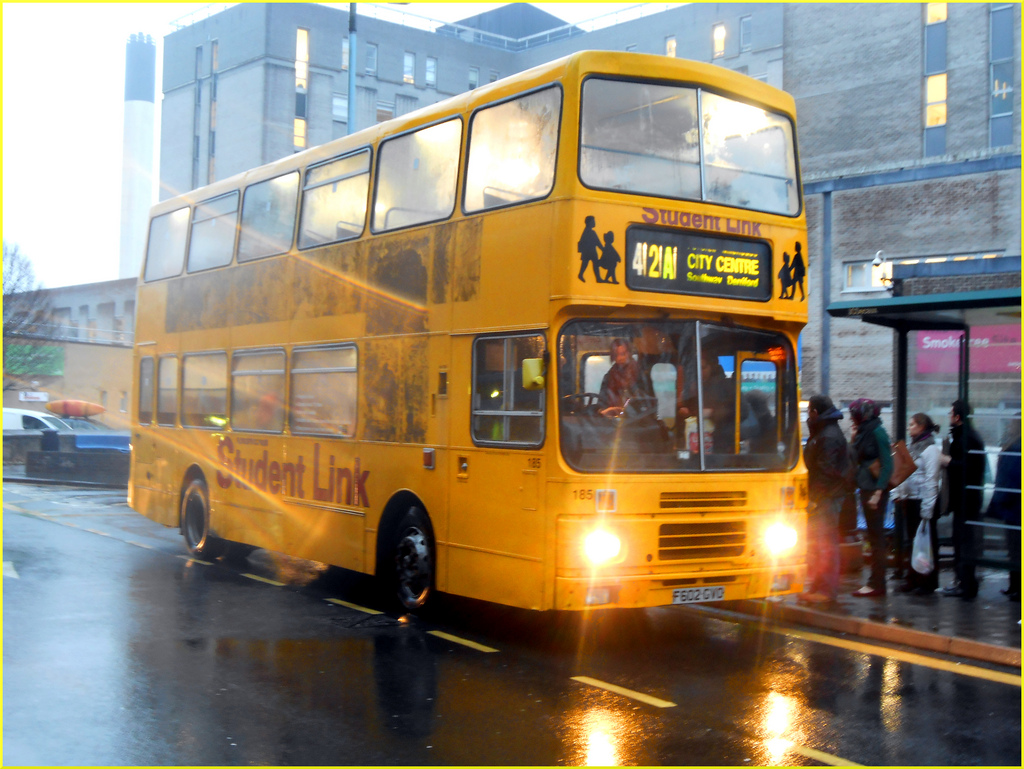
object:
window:
[369, 113, 465, 235]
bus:
[125, 49, 809, 620]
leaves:
[3, 241, 67, 392]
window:
[471, 333, 546, 445]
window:
[288, 346, 359, 438]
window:
[229, 350, 287, 434]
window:
[180, 350, 228, 430]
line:
[788, 745, 865, 766]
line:
[570, 675, 678, 707]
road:
[2, 463, 1021, 766]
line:
[425, 630, 499, 652]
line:
[325, 598, 384, 614]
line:
[240, 573, 288, 587]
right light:
[583, 529, 622, 565]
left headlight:
[758, 518, 800, 559]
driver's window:
[556, 318, 801, 474]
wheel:
[379, 506, 437, 618]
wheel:
[181, 479, 225, 560]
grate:
[658, 491, 747, 561]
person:
[850, 398, 896, 598]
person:
[891, 413, 942, 597]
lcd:
[625, 223, 772, 302]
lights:
[578, 517, 799, 566]